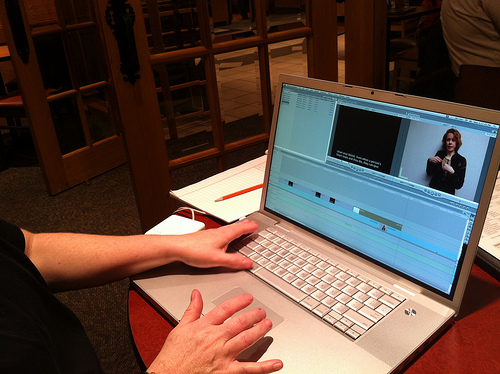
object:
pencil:
[214, 181, 263, 203]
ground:
[317, 124, 345, 165]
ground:
[433, 103, 461, 145]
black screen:
[327, 104, 401, 175]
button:
[341, 308, 375, 331]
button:
[273, 238, 287, 247]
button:
[300, 296, 321, 310]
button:
[254, 267, 309, 306]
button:
[389, 290, 409, 302]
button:
[314, 260, 334, 270]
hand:
[146, 286, 282, 374]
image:
[426, 127, 466, 195]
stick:
[404, 308, 416, 317]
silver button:
[379, 286, 391, 295]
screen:
[263, 80, 498, 295]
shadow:
[457, 270, 496, 317]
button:
[334, 293, 354, 305]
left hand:
[172, 217, 262, 272]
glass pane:
[49, 97, 89, 156]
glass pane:
[32, 32, 75, 98]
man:
[437, 0, 499, 108]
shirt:
[437, 0, 499, 76]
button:
[339, 316, 355, 328]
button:
[330, 301, 351, 314]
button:
[325, 285, 341, 298]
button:
[354, 282, 373, 293]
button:
[323, 265, 342, 276]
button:
[300, 262, 319, 272]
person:
[0, 210, 283, 371]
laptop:
[129, 72, 498, 374]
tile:
[285, 56, 312, 71]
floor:
[161, 36, 348, 140]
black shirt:
[0, 221, 103, 374]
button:
[378, 292, 400, 310]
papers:
[168, 153, 268, 224]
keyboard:
[220, 220, 408, 340]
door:
[100, 0, 342, 236]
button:
[347, 297, 363, 315]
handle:
[103, 0, 142, 80]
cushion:
[0, 88, 58, 105]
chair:
[0, 80, 107, 155]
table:
[128, 201, 500, 374]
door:
[8, 0, 125, 195]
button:
[357, 305, 383, 322]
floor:
[2, 140, 268, 374]